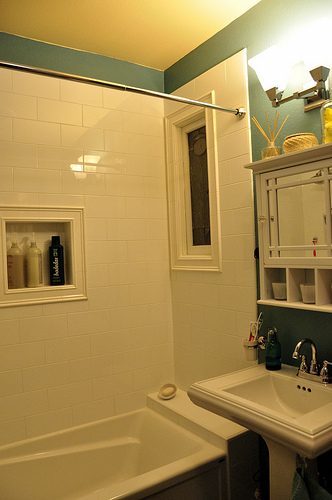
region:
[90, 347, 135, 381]
off white wall tiles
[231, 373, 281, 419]
square white porcelain sink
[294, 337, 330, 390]
chrome faucet over sink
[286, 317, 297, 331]
green wall behind sink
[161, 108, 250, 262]
slim white framed window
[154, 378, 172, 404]
tan soap in soap dish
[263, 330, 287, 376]
green bottle of hand soap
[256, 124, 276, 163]
sticks in clear bottle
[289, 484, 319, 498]
green towel under sink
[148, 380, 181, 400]
soap dish on bathtub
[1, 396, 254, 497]
beige bathtub with soap dish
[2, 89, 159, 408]
beige tile wall in bathroom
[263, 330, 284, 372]
bottle of aftershave sitting on sink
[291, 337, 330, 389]
bathroom sink faucet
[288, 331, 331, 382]
bathroom faucet with handles to turn water on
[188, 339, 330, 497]
bathroom sink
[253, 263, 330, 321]
shelf in bathroom with candles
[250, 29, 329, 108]
light fixtures and lights are on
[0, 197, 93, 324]
group of shampoo and body wash on a bathroom ledge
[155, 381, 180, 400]
the plug of a bathtub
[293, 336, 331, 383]
the faucet of a bathroom sink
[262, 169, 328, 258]
the mirror on a the wall of a bathroom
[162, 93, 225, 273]
the window in a bathroom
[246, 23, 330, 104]
a light over a bathroom sink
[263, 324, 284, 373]
a liquid soap container on a sink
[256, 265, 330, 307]
candles in some shelves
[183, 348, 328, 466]
a white bathroom pedistal sink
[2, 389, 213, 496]
a white bathtub in a bathroom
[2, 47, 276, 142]
a shower curtain rod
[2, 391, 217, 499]
this is a white bath tub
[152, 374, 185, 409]
this is a bar of soap in a dish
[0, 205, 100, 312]
a small shelf in the tile wall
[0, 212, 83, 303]
bottles of soap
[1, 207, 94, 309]
shampoo, conditioner, and body wash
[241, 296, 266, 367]
this is a cup with toothpaste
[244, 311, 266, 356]
a tube of toothpaste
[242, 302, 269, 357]
a toothbrush in the cup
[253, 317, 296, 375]
a bottle of hand soap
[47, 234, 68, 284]
Black bottle of shampoo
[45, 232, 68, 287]
Black bottle of shampoo on shelf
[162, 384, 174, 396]
Bar of soap in white soap tray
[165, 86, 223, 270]
Window in white shower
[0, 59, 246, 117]
Metal bar above bath tub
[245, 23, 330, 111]
Lighting fixture above sink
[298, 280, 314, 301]
White cup below mirror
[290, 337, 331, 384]
Silver faucet on white sink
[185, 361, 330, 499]
White sink next to bath tub